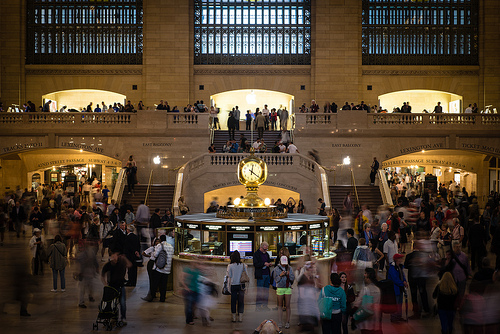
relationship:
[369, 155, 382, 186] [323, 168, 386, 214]
person near staircase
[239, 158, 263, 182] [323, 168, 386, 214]
clock near staircase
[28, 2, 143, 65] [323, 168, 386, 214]
window above staircase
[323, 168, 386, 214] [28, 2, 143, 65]
staircase below window